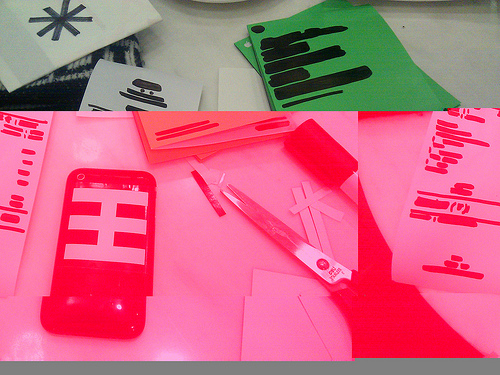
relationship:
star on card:
[28, 2, 91, 42] [2, 1, 161, 90]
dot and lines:
[251, 22, 266, 39] [258, 26, 365, 103]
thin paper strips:
[190, 172, 226, 217] [290, 183, 343, 257]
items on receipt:
[422, 116, 488, 180] [392, 108, 498, 291]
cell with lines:
[47, 166, 157, 305] [64, 188, 148, 264]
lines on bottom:
[154, 119, 229, 142] [147, 115, 298, 167]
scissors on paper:
[215, 185, 431, 356] [241, 267, 344, 360]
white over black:
[77, 187, 145, 204] [117, 204, 147, 221]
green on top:
[355, 26, 395, 62] [234, 0, 392, 52]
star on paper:
[28, 2, 91, 42] [2, 1, 161, 90]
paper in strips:
[294, 179, 320, 249] [290, 183, 343, 257]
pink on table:
[169, 223, 227, 328] [8, 321, 256, 361]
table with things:
[402, 13, 500, 61] [166, 156, 373, 324]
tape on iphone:
[77, 187, 145, 204] [47, 166, 157, 305]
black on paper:
[120, 77, 165, 109] [76, 60, 205, 115]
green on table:
[355, 26, 395, 62] [402, 13, 500, 61]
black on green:
[268, 40, 312, 88] [355, 26, 395, 62]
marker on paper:
[84, 77, 171, 116] [76, 60, 205, 115]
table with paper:
[402, 13, 500, 61] [76, 60, 205, 115]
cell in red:
[47, 166, 157, 305] [31, 226, 231, 336]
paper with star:
[2, 1, 161, 90] [28, 2, 91, 42]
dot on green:
[251, 22, 266, 39] [355, 26, 395, 62]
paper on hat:
[2, 1, 161, 90] [3, 36, 152, 104]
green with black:
[355, 26, 395, 62] [268, 40, 312, 88]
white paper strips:
[294, 179, 320, 249] [290, 183, 343, 257]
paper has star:
[2, 1, 161, 90] [28, 2, 91, 42]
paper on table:
[241, 267, 344, 360] [8, 321, 256, 361]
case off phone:
[31, 290, 159, 335] [47, 166, 157, 305]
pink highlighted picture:
[169, 223, 227, 328] [1, 110, 499, 357]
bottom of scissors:
[328, 250, 384, 341] [215, 185, 431, 356]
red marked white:
[31, 226, 231, 336] [77, 187, 145, 204]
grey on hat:
[123, 40, 138, 66] [3, 36, 152, 104]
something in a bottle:
[290, 122, 349, 187] [283, 118, 361, 203]